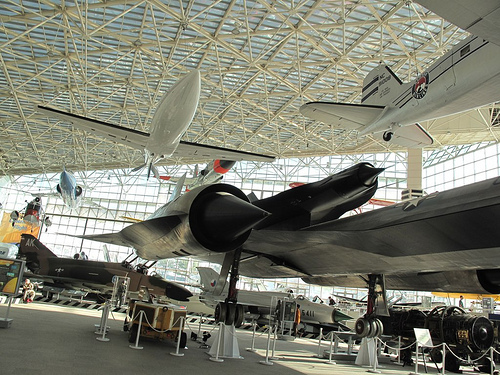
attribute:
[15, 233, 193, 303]
plane — F-4 Phantom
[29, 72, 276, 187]
aircraft — army green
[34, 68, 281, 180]
white plane — white 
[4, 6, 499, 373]
aircraft exhibit — aircraft 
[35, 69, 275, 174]
plane — white 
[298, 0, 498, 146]
plane — white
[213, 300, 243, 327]
wheels — round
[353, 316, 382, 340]
wheels — round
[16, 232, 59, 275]
tail section — jet's 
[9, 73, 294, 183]
plane — white 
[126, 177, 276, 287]
jet engine —  jet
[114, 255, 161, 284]
cockpit — jet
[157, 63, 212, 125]
nose — jet's 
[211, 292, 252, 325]
gears —  jet's landing 